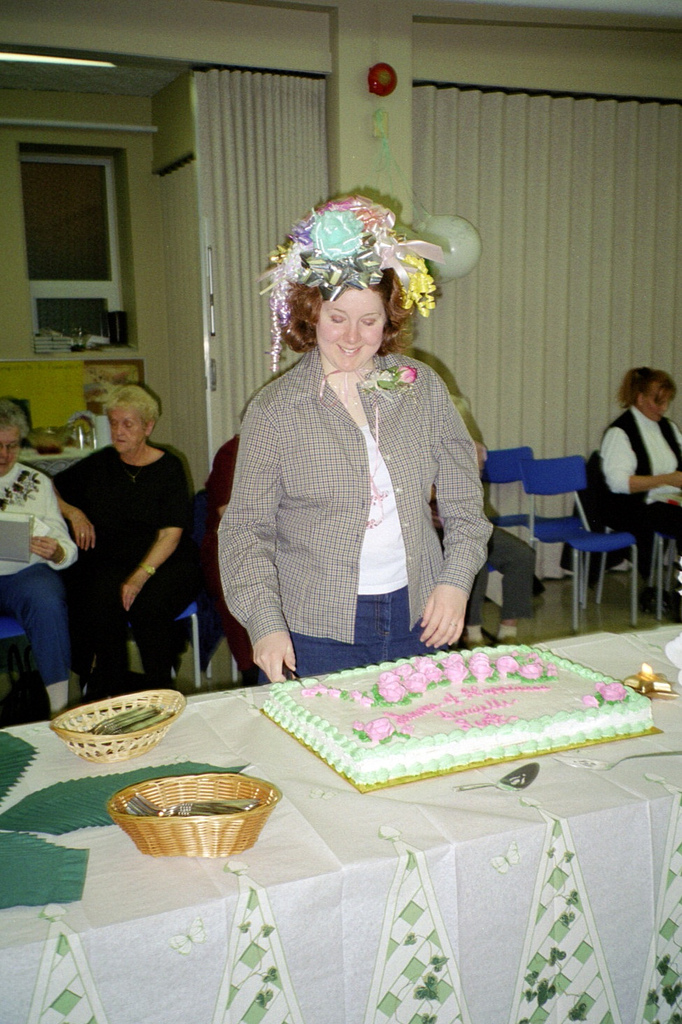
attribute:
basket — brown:
[106, 773, 270, 849]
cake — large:
[263, 650, 669, 812]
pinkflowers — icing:
[306, 633, 628, 742]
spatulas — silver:
[462, 747, 672, 800]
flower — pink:
[347, 360, 419, 409]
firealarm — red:
[364, 44, 398, 92]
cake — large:
[266, 643, 649, 791]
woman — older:
[44, 381, 194, 693]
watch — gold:
[135, 558, 160, 577]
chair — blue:
[501, 433, 629, 600]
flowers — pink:
[386, 635, 510, 716]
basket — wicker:
[125, 752, 284, 885]